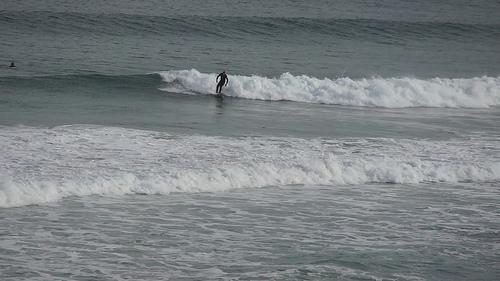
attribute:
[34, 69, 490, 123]
wave — heading toward shore, white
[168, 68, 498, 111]
foam — white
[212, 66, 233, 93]
man — surfing, surfer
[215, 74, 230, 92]
wetsuit — dark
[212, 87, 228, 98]
surfboard — white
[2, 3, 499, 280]
water — gray, ardent, pushy, persistent, powerful, turbulent, rugged, fervent, frothy, foamy, calm, bright white, light blue, lively, rambunctious, assertive, aggressive, zealous, intense, choppy, splashing, engaging, rough, clear, in daytime, at beach, cold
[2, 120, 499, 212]
wave — moving toward beach, white, not large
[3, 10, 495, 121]
waves — large